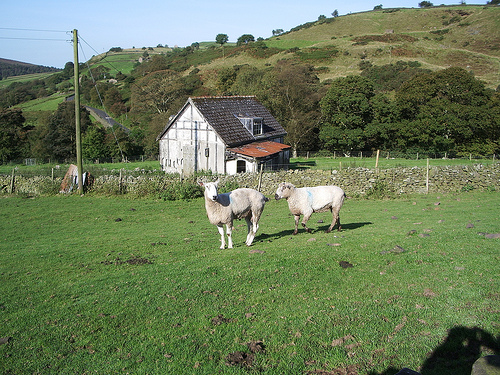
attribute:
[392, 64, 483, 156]
tree — green-leafed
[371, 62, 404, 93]
tree — green-leafed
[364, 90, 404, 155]
tree — green-leafed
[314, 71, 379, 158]
tree — green-leafed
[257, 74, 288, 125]
tree — green-leafed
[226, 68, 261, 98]
tree — green-leafed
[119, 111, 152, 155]
tree — green-leafed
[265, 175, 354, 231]
sheep — white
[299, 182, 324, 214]
spot — blue 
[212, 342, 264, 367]
dirt — small , pile 